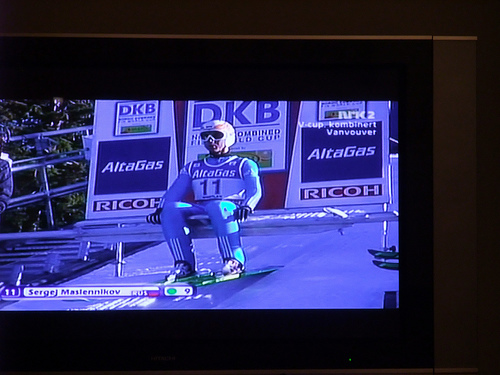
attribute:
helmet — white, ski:
[193, 116, 238, 156]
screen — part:
[46, 97, 409, 317]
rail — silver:
[3, 118, 93, 231]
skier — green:
[141, 118, 281, 278]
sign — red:
[298, 182, 384, 200]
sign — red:
[91, 195, 158, 212]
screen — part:
[0, 98, 400, 309]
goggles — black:
[199, 130, 224, 140]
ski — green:
[153, 265, 198, 285]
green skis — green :
[93, 256, 274, 307]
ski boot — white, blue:
[221, 256, 245, 276]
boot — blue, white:
[150, 225, 200, 287]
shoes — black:
[153, 233, 264, 290]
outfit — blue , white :
[156, 153, 264, 265]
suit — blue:
[147, 148, 261, 290]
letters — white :
[96, 183, 386, 206]